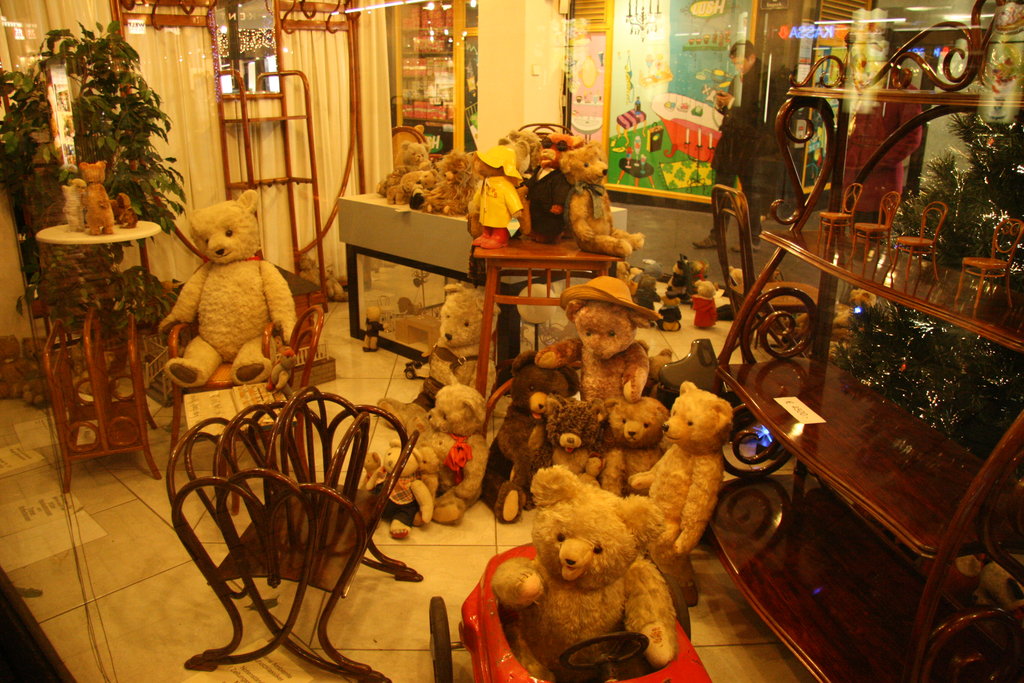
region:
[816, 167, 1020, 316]
row of chairs on the shelf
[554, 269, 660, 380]
teddy bear wearing a hat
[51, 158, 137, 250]
statues on the stand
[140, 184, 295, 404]
teddy bear sitting in a chair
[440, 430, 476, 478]
ribbon around the teddy bears neck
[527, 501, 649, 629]
a teddy bear in a car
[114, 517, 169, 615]
tile on the floor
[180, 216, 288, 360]
a teddy bear sitting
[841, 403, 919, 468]
the wood is brown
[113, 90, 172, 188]
leaves are green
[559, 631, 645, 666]
steering wheel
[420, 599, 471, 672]
tire on the car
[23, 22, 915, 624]
teddy bears on display in a store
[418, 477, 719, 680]
a teddy bear in a toy car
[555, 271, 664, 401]
a teddy bear wearing a brown hat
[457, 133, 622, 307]
teddy bears on a table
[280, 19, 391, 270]
a white curtain with creases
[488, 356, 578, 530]
a dark brown teddy bear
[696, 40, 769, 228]
a man dressed in black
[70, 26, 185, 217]
the green leaves of a plant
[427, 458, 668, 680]
a toy stuffed animal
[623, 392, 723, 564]
a toy stuffed animal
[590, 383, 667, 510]
a toy stuffed animal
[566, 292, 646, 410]
a toy stuffed animal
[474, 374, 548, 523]
a toy stuffed animal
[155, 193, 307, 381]
a toy stuffed animal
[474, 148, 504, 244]
a toy stuffed animal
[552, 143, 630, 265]
a toy stuffed animal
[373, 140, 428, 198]
a toy stuffed animal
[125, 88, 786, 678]
a room filled with teddy bears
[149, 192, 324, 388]
a stuffed bear toy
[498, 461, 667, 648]
a stuffed bear toy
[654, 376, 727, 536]
a stuffed bear toy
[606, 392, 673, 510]
a stuffed bear toy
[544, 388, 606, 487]
a stuffed bear toy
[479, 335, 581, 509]
a stuffed bear toy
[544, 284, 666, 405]
a stuffed bear toy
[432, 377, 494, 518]
a stuffed bear toy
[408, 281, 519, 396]
a stuffed bear toy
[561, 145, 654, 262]
a stuffed bear toy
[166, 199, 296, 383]
the teddy bear is white and brown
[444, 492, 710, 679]
the teddy bear is in a car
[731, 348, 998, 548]
the shelf is made of polished wood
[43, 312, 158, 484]
the magazine organizer is made of wood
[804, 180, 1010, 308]
miniature wood chairs on a shelf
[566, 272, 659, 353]
the teddy bear is wearing a hat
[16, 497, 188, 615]
the floor is made of brown tile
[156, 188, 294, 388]
The large bear is seated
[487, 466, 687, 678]
teddy bear in the car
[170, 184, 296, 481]
bear sitting in a chair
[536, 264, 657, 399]
bear is wearing a hat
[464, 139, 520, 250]
bear is wearing a raincoat and rainhat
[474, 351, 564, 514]
bear is dark brown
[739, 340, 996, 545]
shelf is empty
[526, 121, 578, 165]
bear is wearing sunglasses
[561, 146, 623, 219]
bear has a bow around his neck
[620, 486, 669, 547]
Ear of a teddy bear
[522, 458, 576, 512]
Ear of a teddy bear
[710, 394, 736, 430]
Ear of a teddy bear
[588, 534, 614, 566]
Eye of a bear